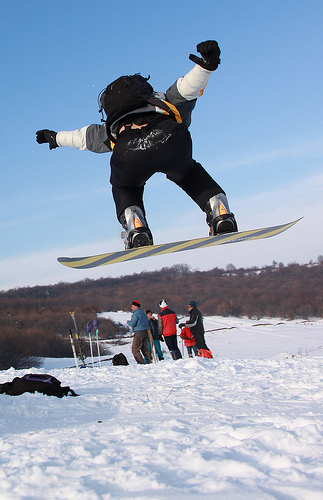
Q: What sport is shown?
A: Snowboarding.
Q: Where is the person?
A: In the air.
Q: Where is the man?
A: In the air.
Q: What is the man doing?
A: Snowboarding.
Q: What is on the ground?
A: Snow.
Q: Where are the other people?
A: In the background on skis.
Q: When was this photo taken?
A: Daytime.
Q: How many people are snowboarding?
A: 1.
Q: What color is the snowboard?
A: Black and yellow.